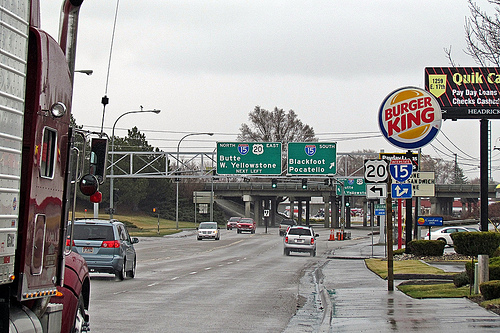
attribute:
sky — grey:
[271, 27, 385, 123]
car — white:
[414, 216, 471, 256]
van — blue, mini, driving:
[51, 202, 142, 282]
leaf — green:
[127, 128, 132, 133]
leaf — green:
[131, 126, 134, 130]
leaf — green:
[141, 132, 144, 137]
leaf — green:
[144, 140, 147, 144]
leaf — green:
[127, 139, 130, 143]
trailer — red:
[11, 1, 91, 331]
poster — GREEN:
[218, 136, 285, 171]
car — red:
[234, 216, 256, 234]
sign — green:
[212, 133, 285, 183]